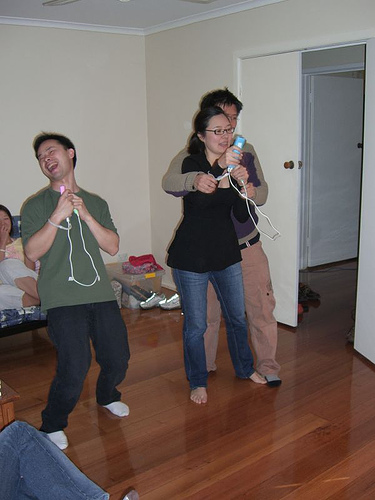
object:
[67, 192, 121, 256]
arm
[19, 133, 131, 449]
man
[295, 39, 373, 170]
open doorway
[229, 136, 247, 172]
remote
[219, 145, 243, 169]
hand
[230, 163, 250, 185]
hand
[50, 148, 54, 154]
eyes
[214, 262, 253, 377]
leg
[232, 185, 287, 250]
white wire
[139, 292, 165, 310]
elephant tail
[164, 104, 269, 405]
lady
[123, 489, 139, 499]
sock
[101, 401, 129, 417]
sock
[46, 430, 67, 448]
sock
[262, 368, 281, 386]
sock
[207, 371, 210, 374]
sock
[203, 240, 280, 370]
pants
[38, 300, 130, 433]
pants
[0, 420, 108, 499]
pants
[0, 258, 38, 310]
pants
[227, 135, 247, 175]
controls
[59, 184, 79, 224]
controls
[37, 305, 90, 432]
leg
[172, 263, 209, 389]
leg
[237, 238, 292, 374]
leg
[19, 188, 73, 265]
arm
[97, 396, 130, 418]
foot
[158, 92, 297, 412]
two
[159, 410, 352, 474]
wood floor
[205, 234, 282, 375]
brown pants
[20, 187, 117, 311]
t-shirt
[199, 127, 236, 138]
eyeglasses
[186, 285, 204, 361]
blue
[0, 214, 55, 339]
couch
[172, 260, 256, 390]
blue jeans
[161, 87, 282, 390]
man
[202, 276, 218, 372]
leg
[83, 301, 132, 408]
leg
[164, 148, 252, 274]
black top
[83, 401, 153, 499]
shadow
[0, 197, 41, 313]
girl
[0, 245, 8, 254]
watch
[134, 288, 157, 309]
reflector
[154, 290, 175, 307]
reflector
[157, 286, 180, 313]
shoe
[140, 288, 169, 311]
shoe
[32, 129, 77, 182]
head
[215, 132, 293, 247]
game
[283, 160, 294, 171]
handle